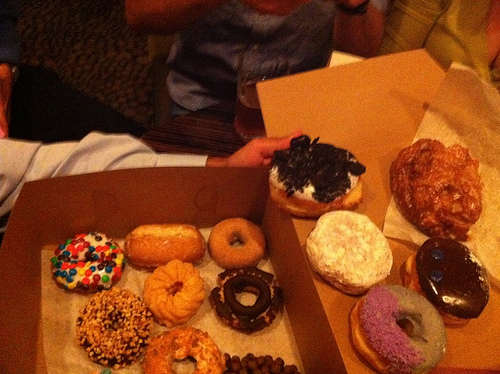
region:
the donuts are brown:
[213, 224, 269, 260]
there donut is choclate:
[231, 275, 291, 332]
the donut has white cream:
[323, 218, 391, 278]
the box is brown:
[30, 171, 326, 371]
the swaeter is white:
[11, 139, 202, 170]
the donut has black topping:
[280, 136, 368, 206]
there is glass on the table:
[231, 76, 272, 150]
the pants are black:
[25, 63, 126, 125]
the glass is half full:
[242, 56, 279, 136]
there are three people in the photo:
[3, 3, 497, 220]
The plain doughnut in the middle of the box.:
[144, 261, 209, 321]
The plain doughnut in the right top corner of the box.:
[210, 211, 266, 263]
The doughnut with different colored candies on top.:
[47, 229, 127, 291]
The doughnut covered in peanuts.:
[77, 293, 155, 368]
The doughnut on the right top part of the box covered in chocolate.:
[406, 232, 490, 319]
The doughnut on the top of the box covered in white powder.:
[303, 203, 395, 287]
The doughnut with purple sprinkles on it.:
[346, 281, 453, 371]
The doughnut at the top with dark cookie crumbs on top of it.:
[268, 126, 370, 211]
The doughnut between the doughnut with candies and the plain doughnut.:
[124, 218, 212, 262]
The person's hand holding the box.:
[208, 131, 310, 159]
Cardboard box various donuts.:
[7, 167, 495, 368]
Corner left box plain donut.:
[198, 217, 273, 262]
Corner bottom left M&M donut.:
[40, 228, 127, 287]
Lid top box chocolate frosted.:
[426, 237, 485, 324]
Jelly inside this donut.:
[305, 209, 400, 292]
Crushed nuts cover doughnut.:
[74, 286, 149, 370]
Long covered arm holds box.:
[3, 123, 308, 190]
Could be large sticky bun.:
[372, 128, 497, 239]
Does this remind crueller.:
[121, 215, 211, 269]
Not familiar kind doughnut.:
[252, 133, 377, 218]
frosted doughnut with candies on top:
[41, 227, 138, 293]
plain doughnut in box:
[124, 217, 211, 264]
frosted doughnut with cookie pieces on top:
[271, 130, 366, 216]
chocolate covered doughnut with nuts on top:
[74, 293, 173, 364]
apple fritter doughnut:
[390, 132, 496, 250]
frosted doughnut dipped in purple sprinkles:
[335, 278, 451, 371]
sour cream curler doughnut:
[140, 254, 213, 325]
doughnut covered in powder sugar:
[301, 201, 404, 298]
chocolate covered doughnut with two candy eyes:
[405, 227, 498, 332]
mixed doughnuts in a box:
[10, 79, 488, 368]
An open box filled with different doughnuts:
[6, 34, 493, 370]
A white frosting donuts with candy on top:
[39, 224, 136, 293]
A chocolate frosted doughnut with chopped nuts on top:
[56, 286, 158, 367]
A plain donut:
[199, 205, 271, 273]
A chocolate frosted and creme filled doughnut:
[394, 223, 491, 337]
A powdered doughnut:
[294, 199, 398, 290]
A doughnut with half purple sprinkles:
[337, 274, 459, 373]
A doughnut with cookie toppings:
[241, 119, 373, 222]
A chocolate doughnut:
[201, 259, 299, 339]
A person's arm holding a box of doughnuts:
[6, 85, 496, 354]